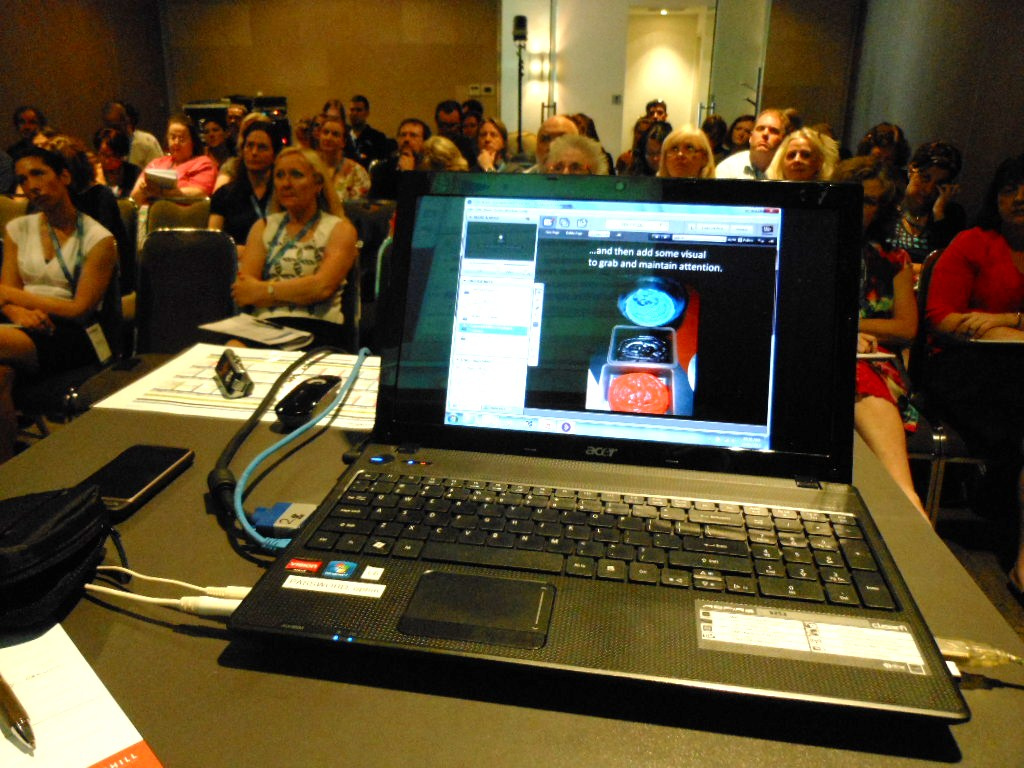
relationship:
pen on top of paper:
[0, 662, 36, 752] [0, 613, 171, 765]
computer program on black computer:
[443, 191, 781, 459] [370, 171, 862, 485]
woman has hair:
[233, 147, 357, 347] [271, 133, 347, 222]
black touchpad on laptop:
[364, 562, 576, 670] [236, 166, 982, 741]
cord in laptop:
[82, 561, 248, 619] [236, 166, 982, 741]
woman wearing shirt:
[137, 109, 215, 209] [141, 153, 219, 201]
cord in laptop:
[206, 346, 373, 569] [289, 122, 912, 742]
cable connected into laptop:
[949, 616, 1003, 696] [236, 166, 982, 741]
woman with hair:
[233, 147, 357, 347] [277, 143, 351, 223]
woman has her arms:
[261, 138, 380, 325] [235, 217, 359, 308]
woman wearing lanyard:
[229, 137, 361, 328] [268, 208, 318, 269]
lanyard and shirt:
[268, 208, 318, 269] [257, 208, 342, 321]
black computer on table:
[401, 205, 813, 452] [8, 336, 992, 762]